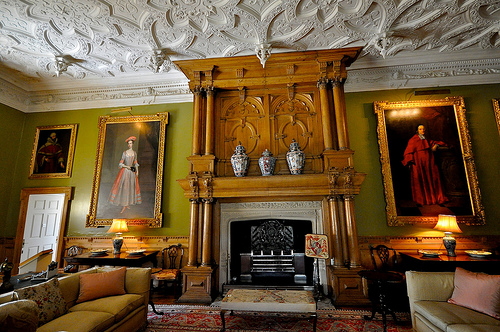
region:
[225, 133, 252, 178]
Large vase above the fire place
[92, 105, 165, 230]
painting of a woman on the wall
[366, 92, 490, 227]
painting of a man on the wall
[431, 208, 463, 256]
Lamp on the table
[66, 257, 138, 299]
Brown pillow on the sofa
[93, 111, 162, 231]
Large painting on the wall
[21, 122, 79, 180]
small painting on the wall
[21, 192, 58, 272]
White door in the frame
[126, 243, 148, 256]
plate on the table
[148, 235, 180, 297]
chair next to the table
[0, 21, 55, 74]
white design on ceiling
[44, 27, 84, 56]
white design on ceiling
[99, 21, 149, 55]
white design on ceiling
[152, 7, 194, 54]
white design on ceiling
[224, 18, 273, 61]
white design on ceiling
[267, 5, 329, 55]
white design on ceiling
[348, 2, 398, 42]
white design on ceiling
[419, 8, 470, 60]
white design on ceiling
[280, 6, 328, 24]
white design on ceiling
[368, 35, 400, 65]
white design on ceiling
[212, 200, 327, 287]
a large fireplace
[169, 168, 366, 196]
a brown fireplace mantle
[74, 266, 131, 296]
an orange decorative pillow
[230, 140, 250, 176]
a large gray vase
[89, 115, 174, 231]
a large picture frame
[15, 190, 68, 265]
part of a white door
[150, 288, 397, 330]
part of a red area rug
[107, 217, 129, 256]
a table lamp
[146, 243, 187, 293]
a wooden chair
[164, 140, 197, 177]
part of a painted green wall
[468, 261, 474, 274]
part of a chair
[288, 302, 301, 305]
part of a table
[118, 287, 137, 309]
part of a pillow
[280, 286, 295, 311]
part of a table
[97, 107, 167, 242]
old picture of woman on the wall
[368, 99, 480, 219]
picture of man on the wall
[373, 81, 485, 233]
frame with gold trim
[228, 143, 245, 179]
urn on fireplace mantle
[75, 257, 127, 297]
peach throw pillow on sofa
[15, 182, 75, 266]
white door with wood frame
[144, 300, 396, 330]
large area rug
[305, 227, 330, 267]
sign in front of fireplace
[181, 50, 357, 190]
mantle made from wood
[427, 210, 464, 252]
lamp on top of table